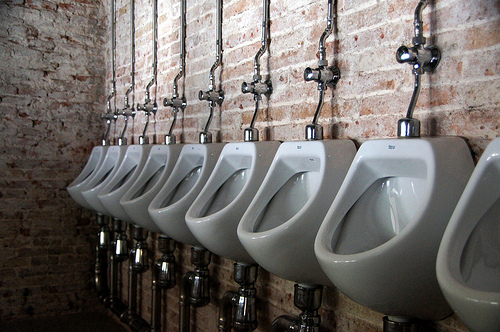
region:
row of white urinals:
[48, 93, 485, 313]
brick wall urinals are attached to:
[105, 5, 495, 320]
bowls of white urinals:
[77, 159, 499, 292]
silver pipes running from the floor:
[91, 217, 348, 330]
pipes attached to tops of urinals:
[94, 5, 479, 132]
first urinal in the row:
[434, 123, 499, 329]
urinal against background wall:
[60, 133, 102, 218]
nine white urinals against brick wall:
[52, 127, 495, 327]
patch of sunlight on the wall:
[100, 5, 289, 127]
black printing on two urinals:
[291, 141, 400, 154]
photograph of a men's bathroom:
[21, 8, 487, 310]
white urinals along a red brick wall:
[80, 3, 492, 305]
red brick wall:
[22, 0, 480, 307]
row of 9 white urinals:
[57, 105, 492, 302]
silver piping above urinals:
[97, 0, 454, 145]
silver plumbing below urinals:
[84, 214, 424, 321]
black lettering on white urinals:
[379, 138, 402, 155]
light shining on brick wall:
[126, 2, 335, 96]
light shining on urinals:
[230, 128, 435, 240]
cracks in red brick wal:
[35, 31, 97, 101]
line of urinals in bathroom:
[60, 100, 475, 238]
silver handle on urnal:
[385, 42, 440, 74]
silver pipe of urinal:
[397, 83, 420, 114]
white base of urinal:
[290, 137, 452, 314]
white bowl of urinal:
[305, 143, 453, 288]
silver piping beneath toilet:
[298, 282, 314, 325]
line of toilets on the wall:
[125, 136, 366, 228]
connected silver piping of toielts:
[90, 253, 158, 314]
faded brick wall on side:
[10, 16, 87, 140]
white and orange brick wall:
[248, 9, 383, 90]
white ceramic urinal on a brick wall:
[66, 144, 106, 208]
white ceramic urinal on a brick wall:
[81, 145, 125, 211]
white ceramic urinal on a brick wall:
[99, 143, 149, 222]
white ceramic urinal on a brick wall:
[120, 143, 181, 233]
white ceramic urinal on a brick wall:
[150, 143, 220, 245]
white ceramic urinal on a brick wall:
[185, 140, 282, 262]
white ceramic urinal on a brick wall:
[235, 140, 356, 286]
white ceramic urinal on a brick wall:
[316, 138, 473, 321]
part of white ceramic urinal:
[436, 138, 498, 329]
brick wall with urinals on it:
[103, 0, 499, 330]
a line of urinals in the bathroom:
[65, 130, 499, 326]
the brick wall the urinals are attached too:
[105, 3, 497, 329]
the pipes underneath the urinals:
[88, 217, 338, 329]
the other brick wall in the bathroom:
[6, 5, 111, 320]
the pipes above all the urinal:
[106, 3, 449, 137]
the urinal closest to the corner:
[66, 139, 100, 214]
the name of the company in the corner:
[384, 140, 396, 150]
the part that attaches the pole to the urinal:
[394, 118, 417, 138]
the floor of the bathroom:
[6, 304, 138, 329]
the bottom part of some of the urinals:
[71, 189, 236, 259]